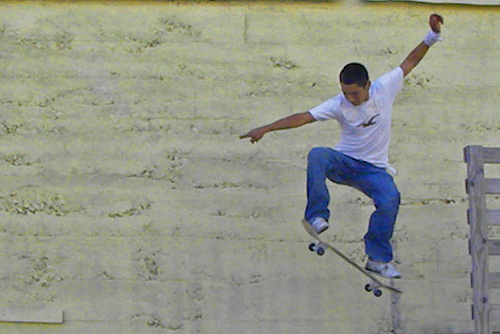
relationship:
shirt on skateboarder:
[307, 66, 405, 176] [225, 28, 452, 298]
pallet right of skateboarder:
[462, 142, 496, 332] [225, 28, 452, 298]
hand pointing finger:
[237, 130, 264, 142] [235, 132, 249, 140]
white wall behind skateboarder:
[24, 31, 229, 288] [225, 28, 452, 298]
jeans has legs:
[302, 145, 399, 264] [304, 142, 404, 272]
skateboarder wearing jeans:
[225, 28, 452, 298] [302, 145, 399, 264]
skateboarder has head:
[225, 28, 452, 298] [335, 59, 377, 107]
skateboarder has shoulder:
[225, 28, 452, 298] [325, 92, 342, 125]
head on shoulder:
[335, 59, 377, 107] [325, 92, 342, 125]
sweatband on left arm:
[424, 30, 440, 45] [388, 13, 443, 98]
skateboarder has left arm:
[225, 28, 452, 298] [388, 13, 443, 98]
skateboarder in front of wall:
[301, 216, 402, 298] [52, 73, 254, 302]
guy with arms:
[240, 12, 444, 278] [240, 12, 442, 142]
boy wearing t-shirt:
[238, 13, 443, 278] [307, 66, 404, 178]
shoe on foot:
[305, 217, 330, 238] [250, 161, 429, 281]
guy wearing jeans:
[240, 12, 444, 278] [302, 145, 399, 264]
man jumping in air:
[268, 61, 482, 282] [47, 39, 482, 332]